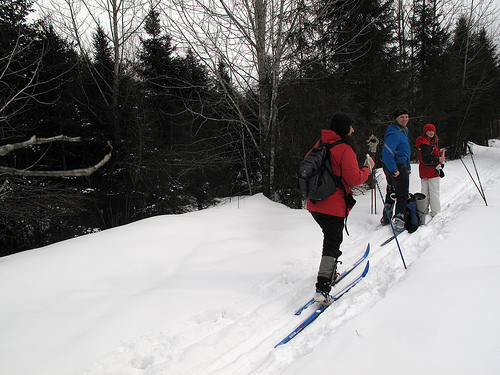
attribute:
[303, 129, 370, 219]
jacket — red, blue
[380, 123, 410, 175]
jacket — blue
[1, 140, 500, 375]
snow — PATCH , white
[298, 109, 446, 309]
people — skiing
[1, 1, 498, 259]
trees — evergreen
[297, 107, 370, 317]
woman — skiing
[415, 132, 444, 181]
jacket — red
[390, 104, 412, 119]
hat — black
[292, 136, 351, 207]
backpack — grey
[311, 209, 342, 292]
pants — black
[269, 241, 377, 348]
skis — blue